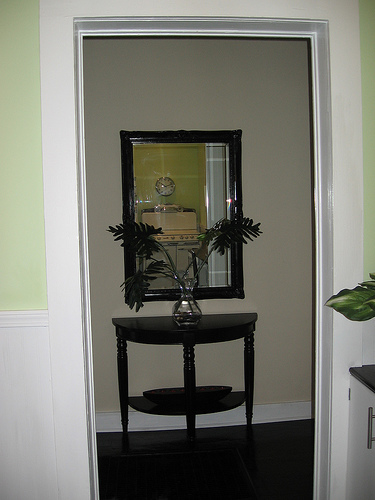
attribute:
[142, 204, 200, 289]
refrigerator — white, small, reflected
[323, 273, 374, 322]
leaf — green, big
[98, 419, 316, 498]
floor — black, shiny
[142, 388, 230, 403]
bowl — long, black, shallow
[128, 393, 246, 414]
shelf — half circle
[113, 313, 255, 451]
stand — black, small, brown, wood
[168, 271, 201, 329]
vase — clear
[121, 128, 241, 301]
mirror — dark brown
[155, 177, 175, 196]
clock — grey, round, reflected, silver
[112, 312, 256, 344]
shelf — half circle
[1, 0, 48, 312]
wall — pale green, pale yellow, light green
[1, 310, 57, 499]
border — white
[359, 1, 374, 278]
wall — pale green, pale yellow, light green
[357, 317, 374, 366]
border — white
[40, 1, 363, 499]
door frame — white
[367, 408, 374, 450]
handle — silver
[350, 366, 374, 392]
countertop — black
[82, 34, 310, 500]
doorway — centered